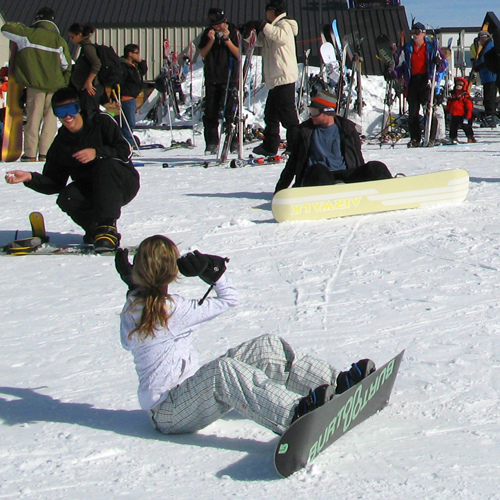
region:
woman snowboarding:
[76, 227, 478, 499]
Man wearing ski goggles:
[4, 32, 131, 254]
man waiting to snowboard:
[280, 62, 477, 257]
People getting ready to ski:
[191, 9, 286, 170]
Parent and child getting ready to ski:
[386, 22, 499, 148]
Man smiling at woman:
[8, 84, 145, 255]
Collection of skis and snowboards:
[314, 19, 370, 104]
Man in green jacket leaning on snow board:
[0, 5, 89, 160]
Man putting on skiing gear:
[194, 10, 252, 164]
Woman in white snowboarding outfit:
[124, 228, 396, 487]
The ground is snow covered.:
[325, 244, 490, 345]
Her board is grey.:
[258, 351, 436, 476]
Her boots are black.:
[290, 330, 373, 437]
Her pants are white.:
[163, 344, 310, 455]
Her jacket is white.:
[100, 262, 240, 397]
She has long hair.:
[113, 222, 205, 336]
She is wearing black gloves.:
[90, 234, 286, 309]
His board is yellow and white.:
[253, 158, 482, 205]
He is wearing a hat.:
[291, 87, 348, 137]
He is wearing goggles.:
[278, 77, 368, 147]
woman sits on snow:
[95, 228, 381, 460]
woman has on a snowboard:
[106, 227, 423, 477]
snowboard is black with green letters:
[250, 337, 422, 484]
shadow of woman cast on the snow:
[3, 370, 243, 465]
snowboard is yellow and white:
[258, 163, 473, 225]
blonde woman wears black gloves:
[88, 230, 238, 345]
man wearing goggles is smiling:
[1, 77, 148, 253]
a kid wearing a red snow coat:
[435, 69, 484, 150]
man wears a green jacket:
[0, 9, 79, 113]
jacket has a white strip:
[0, 15, 81, 101]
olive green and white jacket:
[1, 13, 71, 93]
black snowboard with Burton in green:
[273, 348, 408, 478]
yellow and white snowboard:
[271, 169, 469, 221]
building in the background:
[3, 2, 410, 100]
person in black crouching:
[7, 86, 140, 252]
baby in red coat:
[445, 73, 476, 147]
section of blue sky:
[402, 1, 497, 32]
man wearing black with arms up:
[198, 6, 242, 166]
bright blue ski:
[329, 16, 342, 52]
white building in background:
[434, 22, 487, 77]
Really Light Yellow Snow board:
[269, 164, 482, 227]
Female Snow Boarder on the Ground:
[96, 228, 426, 475]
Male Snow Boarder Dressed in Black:
[0, 71, 150, 269]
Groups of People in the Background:
[0, 2, 499, 159]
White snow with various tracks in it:
[286, 227, 497, 332]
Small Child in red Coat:
[441, 74, 486, 145]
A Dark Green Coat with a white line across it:
[3, 11, 80, 98]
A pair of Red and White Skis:
[218, 28, 251, 160]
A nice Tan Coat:
[263, 15, 297, 83]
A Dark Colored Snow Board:
[273, 357, 432, 480]